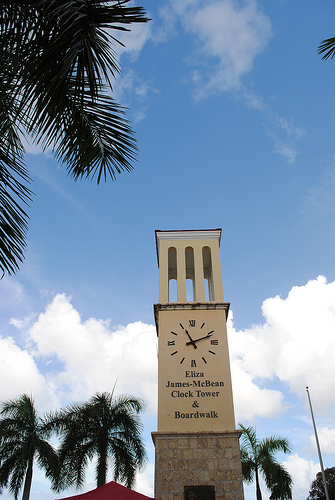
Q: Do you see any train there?
A: No, there are no trains.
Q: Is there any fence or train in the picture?
A: No, there are no trains or fences.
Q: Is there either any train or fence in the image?
A: No, there are no trains or fences.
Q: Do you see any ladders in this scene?
A: No, there are no ladders.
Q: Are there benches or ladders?
A: No, there are no ladders or benches.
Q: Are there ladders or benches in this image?
A: No, there are no ladders or benches.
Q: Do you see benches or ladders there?
A: No, there are no ladders or benches.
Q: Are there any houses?
A: No, there are no houses.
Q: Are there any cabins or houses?
A: No, there are no houses or cabins.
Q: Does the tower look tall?
A: Yes, the tower is tall.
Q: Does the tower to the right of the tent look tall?
A: Yes, the tower is tall.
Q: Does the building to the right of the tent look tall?
A: Yes, the tower is tall.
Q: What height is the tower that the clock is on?
A: The tower is tall.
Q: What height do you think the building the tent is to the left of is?
A: The tower is tall.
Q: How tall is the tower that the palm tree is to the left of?
A: The tower is tall.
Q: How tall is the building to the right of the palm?
A: The tower is tall.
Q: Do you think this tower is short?
A: No, the tower is tall.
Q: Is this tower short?
A: No, the tower is tall.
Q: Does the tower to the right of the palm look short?
A: No, the tower is tall.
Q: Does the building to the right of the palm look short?
A: No, the tower is tall.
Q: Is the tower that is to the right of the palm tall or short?
A: The tower is tall.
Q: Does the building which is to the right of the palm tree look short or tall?
A: The tower is tall.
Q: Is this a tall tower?
A: Yes, this is a tall tower.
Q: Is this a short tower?
A: No, this is a tall tower.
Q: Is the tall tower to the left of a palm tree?
A: No, the tower is to the right of a palm tree.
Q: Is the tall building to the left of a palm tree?
A: No, the tower is to the right of a palm tree.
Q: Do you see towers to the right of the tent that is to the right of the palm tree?
A: Yes, there is a tower to the right of the tent.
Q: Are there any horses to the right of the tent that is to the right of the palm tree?
A: No, there is a tower to the right of the tent.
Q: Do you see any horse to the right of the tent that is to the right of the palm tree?
A: No, there is a tower to the right of the tent.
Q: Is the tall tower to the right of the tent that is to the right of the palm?
A: Yes, the tower is to the right of the tent.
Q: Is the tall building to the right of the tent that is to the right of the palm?
A: Yes, the tower is to the right of the tent.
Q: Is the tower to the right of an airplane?
A: No, the tower is to the right of the tent.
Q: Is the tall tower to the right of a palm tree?
A: Yes, the tower is to the right of a palm tree.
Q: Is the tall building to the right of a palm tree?
A: Yes, the tower is to the right of a palm tree.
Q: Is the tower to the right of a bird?
A: No, the tower is to the right of a palm tree.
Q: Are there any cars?
A: No, there are no cars.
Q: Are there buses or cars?
A: No, there are no cars or buses.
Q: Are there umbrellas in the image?
A: No, there are no umbrellas.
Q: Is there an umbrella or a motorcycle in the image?
A: No, there are no umbrellas or motorcycles.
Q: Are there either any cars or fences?
A: No, there are no fences or cars.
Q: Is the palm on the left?
A: Yes, the palm is on the left of the image.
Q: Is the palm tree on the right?
A: No, the palm tree is on the left of the image.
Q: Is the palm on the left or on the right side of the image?
A: The palm is on the left of the image.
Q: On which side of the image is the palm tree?
A: The palm tree is on the left of the image.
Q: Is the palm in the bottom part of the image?
A: Yes, the palm is in the bottom of the image.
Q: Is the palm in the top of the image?
A: No, the palm is in the bottom of the image.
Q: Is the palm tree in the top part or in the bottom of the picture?
A: The palm tree is in the bottom of the image.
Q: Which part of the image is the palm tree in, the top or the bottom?
A: The palm tree is in the bottom of the image.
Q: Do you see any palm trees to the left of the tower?
A: Yes, there is a palm tree to the left of the tower.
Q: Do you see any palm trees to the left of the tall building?
A: Yes, there is a palm tree to the left of the tower.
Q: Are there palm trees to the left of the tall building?
A: Yes, there is a palm tree to the left of the tower.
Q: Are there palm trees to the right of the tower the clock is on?
A: No, the palm tree is to the left of the tower.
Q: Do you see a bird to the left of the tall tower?
A: No, there is a palm tree to the left of the tower.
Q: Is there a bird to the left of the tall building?
A: No, there is a palm tree to the left of the tower.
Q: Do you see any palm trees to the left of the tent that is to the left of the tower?
A: Yes, there is a palm tree to the left of the tent.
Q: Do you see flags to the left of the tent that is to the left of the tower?
A: No, there is a palm tree to the left of the tent.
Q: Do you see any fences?
A: No, there are no fences.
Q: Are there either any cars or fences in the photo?
A: No, there are no fences or cars.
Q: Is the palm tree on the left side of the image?
A: Yes, the palm tree is on the left of the image.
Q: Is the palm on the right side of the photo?
A: No, the palm is on the left of the image.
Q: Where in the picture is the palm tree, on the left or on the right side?
A: The palm tree is on the left of the image.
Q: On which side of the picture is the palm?
A: The palm is on the left of the image.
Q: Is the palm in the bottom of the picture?
A: Yes, the palm is in the bottom of the image.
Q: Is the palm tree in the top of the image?
A: No, the palm tree is in the bottom of the image.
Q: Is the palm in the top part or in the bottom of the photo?
A: The palm is in the bottom of the image.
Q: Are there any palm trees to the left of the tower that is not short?
A: Yes, there is a palm tree to the left of the tower.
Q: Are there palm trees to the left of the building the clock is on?
A: Yes, there is a palm tree to the left of the tower.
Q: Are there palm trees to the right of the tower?
A: No, the palm tree is to the left of the tower.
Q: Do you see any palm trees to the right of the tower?
A: No, the palm tree is to the left of the tower.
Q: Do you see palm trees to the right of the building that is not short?
A: No, the palm tree is to the left of the tower.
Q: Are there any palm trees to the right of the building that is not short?
A: No, the palm tree is to the left of the tower.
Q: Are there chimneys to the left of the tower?
A: No, there is a palm tree to the left of the tower.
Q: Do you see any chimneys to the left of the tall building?
A: No, there is a palm tree to the left of the tower.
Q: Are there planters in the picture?
A: No, there are no planters.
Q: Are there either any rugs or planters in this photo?
A: No, there are no planters or rugs.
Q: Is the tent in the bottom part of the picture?
A: Yes, the tent is in the bottom of the image.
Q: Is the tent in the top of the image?
A: No, the tent is in the bottom of the image.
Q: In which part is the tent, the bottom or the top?
A: The tent is in the bottom of the image.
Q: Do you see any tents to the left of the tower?
A: Yes, there is a tent to the left of the tower.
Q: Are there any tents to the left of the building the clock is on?
A: Yes, there is a tent to the left of the tower.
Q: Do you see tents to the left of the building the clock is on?
A: Yes, there is a tent to the left of the tower.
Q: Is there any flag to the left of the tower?
A: No, there is a tent to the left of the tower.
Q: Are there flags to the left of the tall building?
A: No, there is a tent to the left of the tower.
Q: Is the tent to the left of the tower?
A: Yes, the tent is to the left of the tower.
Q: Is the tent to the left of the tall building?
A: Yes, the tent is to the left of the tower.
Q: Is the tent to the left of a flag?
A: No, the tent is to the left of the tower.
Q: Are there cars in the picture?
A: No, there are no cars.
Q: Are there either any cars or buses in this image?
A: No, there are no cars or buses.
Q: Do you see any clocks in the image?
A: Yes, there is a clock.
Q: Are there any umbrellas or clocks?
A: Yes, there is a clock.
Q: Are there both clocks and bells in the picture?
A: No, there is a clock but no bells.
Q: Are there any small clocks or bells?
A: Yes, there is a small clock.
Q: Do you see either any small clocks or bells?
A: Yes, there is a small clock.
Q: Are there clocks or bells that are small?
A: Yes, the clock is small.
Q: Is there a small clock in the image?
A: Yes, there is a small clock.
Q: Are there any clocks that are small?
A: Yes, there is a clock that is small.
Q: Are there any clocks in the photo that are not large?
A: Yes, there is a small clock.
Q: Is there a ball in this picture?
A: No, there are no balls.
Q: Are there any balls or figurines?
A: No, there are no balls or figurines.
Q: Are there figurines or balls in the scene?
A: No, there are no balls or figurines.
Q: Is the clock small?
A: Yes, the clock is small.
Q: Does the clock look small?
A: Yes, the clock is small.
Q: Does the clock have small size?
A: Yes, the clock is small.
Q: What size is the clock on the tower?
A: The clock is small.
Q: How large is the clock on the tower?
A: The clock is small.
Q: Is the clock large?
A: No, the clock is small.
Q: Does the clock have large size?
A: No, the clock is small.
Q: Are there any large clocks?
A: No, there is a clock but it is small.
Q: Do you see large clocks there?
A: No, there is a clock but it is small.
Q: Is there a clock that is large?
A: No, there is a clock but it is small.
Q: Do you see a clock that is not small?
A: No, there is a clock but it is small.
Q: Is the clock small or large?
A: The clock is small.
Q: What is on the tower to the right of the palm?
A: The clock is on the tower.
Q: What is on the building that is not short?
A: The clock is on the tower.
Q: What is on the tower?
A: The clock is on the tower.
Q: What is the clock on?
A: The clock is on the tower.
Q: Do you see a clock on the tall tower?
A: Yes, there is a clock on the tower.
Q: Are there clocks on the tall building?
A: Yes, there is a clock on the tower.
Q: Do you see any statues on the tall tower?
A: No, there is a clock on the tower.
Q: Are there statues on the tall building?
A: No, there is a clock on the tower.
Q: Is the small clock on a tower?
A: Yes, the clock is on a tower.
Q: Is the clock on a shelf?
A: No, the clock is on a tower.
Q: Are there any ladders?
A: No, there are no ladders.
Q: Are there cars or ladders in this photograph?
A: No, there are no ladders or cars.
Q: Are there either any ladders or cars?
A: No, there are no ladders or cars.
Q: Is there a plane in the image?
A: No, there are no airplanes.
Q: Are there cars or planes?
A: No, there are no planes or cars.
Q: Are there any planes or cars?
A: No, there are no planes or cars.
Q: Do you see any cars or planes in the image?
A: No, there are no planes or cars.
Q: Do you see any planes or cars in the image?
A: No, there are no planes or cars.